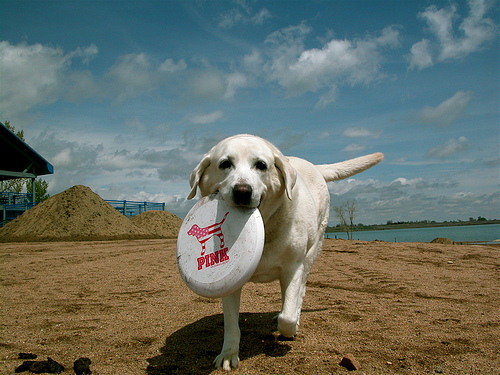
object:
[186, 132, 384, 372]
dog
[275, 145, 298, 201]
ear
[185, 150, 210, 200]
ear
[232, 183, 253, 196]
nose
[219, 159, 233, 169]
eye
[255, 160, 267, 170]
eye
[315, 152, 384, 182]
tail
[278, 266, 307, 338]
leg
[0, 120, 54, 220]
building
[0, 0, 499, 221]
sky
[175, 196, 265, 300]
frisbee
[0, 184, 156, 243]
sand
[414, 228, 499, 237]
water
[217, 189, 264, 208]
mouth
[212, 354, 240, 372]
paw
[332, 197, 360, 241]
tree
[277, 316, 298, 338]
paw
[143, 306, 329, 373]
shadow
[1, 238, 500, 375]
sand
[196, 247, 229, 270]
word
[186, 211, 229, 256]
dog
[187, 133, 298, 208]
head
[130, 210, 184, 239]
dirt